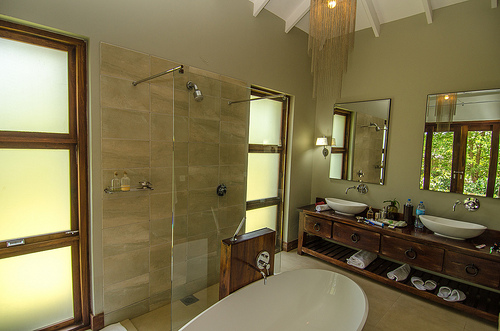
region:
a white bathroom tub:
[134, 213, 369, 330]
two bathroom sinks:
[297, 156, 498, 243]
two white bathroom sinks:
[312, 165, 492, 252]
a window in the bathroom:
[212, 67, 324, 250]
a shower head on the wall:
[179, 75, 224, 124]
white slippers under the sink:
[396, 249, 474, 319]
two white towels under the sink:
[321, 213, 422, 301]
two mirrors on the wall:
[297, 71, 499, 206]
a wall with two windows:
[294, 75, 496, 201]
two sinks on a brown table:
[254, 125, 499, 309]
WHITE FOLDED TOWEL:
[344, 247, 377, 269]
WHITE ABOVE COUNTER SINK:
[322, 193, 368, 217]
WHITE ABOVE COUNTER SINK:
[417, 209, 487, 245]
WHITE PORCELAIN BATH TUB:
[164, 264, 371, 329]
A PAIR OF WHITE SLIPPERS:
[409, 274, 436, 292]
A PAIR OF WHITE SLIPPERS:
[436, 284, 468, 304]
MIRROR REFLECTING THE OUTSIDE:
[414, 89, 497, 197]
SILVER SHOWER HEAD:
[185, 79, 205, 104]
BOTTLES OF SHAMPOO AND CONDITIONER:
[109, 170, 131, 193]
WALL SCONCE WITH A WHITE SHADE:
[313, 134, 329, 159]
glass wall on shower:
[150, 59, 241, 294]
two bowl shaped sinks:
[312, 193, 487, 240]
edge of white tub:
[282, 252, 377, 326]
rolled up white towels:
[334, 248, 414, 285]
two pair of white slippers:
[405, 274, 468, 304]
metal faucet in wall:
[445, 194, 479, 220]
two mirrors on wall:
[338, 76, 482, 194]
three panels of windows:
[8, 27, 103, 309]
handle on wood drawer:
[335, 229, 368, 247]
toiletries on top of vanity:
[367, 195, 428, 226]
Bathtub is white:
[160, 260, 370, 329]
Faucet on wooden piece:
[253, 250, 275, 283]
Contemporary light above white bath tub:
[294, 0, 369, 109]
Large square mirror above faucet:
[322, 95, 391, 184]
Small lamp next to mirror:
[312, 136, 332, 159]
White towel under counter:
[342, 245, 378, 270]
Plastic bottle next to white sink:
[412, 197, 427, 232]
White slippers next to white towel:
[410, 269, 438, 295]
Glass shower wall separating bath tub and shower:
[170, 65, 287, 327]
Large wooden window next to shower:
[1, 20, 82, 330]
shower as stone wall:
[95, 38, 249, 324]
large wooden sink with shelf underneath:
[295, 200, 499, 327]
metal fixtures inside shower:
[102, 62, 228, 199]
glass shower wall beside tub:
[167, 57, 284, 329]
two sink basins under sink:
[323, 178, 490, 246]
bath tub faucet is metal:
[253, 251, 273, 283]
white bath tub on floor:
[172, 266, 369, 329]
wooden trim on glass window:
[0, 22, 91, 329]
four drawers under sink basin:
[305, 216, 497, 287]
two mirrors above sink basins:
[326, 85, 498, 200]